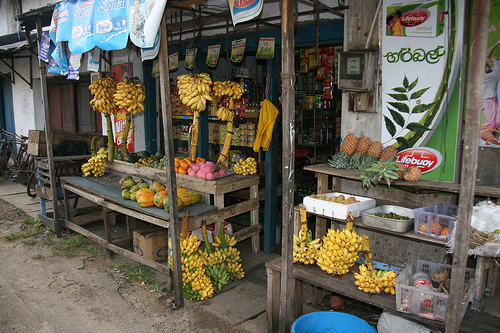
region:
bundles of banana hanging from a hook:
[87, 55, 140, 146]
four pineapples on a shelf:
[310, 125, 407, 192]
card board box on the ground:
[102, 225, 172, 285]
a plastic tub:
[408, 196, 456, 244]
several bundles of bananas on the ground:
[142, 220, 244, 306]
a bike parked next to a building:
[1, 121, 32, 159]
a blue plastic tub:
[270, 310, 393, 331]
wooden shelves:
[45, 126, 255, 276]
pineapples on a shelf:
[335, 120, 477, 196]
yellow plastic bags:
[242, 87, 280, 181]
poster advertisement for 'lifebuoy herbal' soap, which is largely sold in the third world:
[380, 1, 467, 185]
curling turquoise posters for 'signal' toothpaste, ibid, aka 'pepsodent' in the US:
[29, 0, 164, 91]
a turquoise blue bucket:
[282, 305, 380, 330]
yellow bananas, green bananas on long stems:
[195, 212, 231, 288]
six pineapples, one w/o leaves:
[325, 128, 426, 198]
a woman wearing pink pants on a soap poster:
[475, 32, 497, 143]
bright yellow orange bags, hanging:
[245, 90, 280, 155]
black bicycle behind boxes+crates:
[0, 123, 105, 228]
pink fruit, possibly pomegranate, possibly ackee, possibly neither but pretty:
[180, 156, 227, 182]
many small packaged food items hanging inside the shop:
[296, 46, 342, 110]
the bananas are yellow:
[314, 221, 361, 282]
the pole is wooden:
[268, 41, 298, 293]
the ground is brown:
[18, 256, 85, 321]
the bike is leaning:
[6, 120, 28, 176]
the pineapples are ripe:
[323, 131, 421, 187]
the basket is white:
[366, 209, 406, 232]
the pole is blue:
[260, 159, 279, 256]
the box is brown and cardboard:
[128, 230, 166, 263]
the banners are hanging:
[194, 36, 278, 70]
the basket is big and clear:
[398, 272, 455, 319]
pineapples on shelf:
[325, 135, 428, 189]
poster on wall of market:
[384, 2, 469, 179]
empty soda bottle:
[407, 275, 442, 315]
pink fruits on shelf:
[184, 157, 228, 182]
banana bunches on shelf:
[290, 200, 402, 299]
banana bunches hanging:
[85, 72, 247, 164]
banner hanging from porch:
[45, 0, 172, 57]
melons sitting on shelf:
[113, 173, 209, 209]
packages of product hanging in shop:
[296, 45, 338, 110]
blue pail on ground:
[285, 306, 375, 331]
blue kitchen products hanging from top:
[25, 0, 145, 75]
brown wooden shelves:
[260, 155, 495, 325]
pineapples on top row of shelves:
[330, 130, 422, 175]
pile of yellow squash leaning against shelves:
[167, 215, 247, 300]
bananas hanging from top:
[75, 68, 251, 128]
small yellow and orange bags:
[296, 46, 335, 109]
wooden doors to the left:
[40, 70, 105, 170]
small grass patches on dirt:
[14, 213, 174, 308]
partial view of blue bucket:
[281, 310, 383, 330]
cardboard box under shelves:
[126, 228, 174, 274]